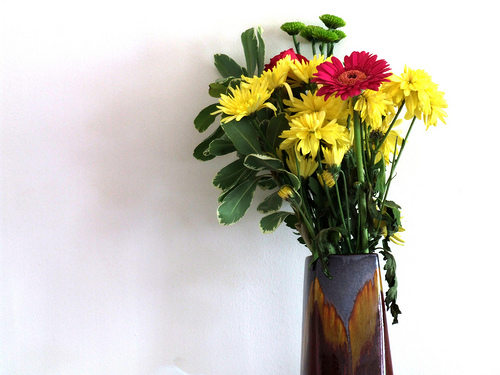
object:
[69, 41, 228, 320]
shadow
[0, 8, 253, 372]
wall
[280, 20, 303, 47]
flower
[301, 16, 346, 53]
flower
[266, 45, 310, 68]
flower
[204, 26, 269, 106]
leaves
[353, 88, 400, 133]
flower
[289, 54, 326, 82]
flower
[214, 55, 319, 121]
flower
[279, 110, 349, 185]
flower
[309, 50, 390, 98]
daisy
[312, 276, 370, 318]
painting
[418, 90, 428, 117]
petals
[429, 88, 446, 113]
petals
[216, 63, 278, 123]
daisies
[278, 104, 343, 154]
daisies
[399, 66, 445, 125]
daisies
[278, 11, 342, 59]
flowers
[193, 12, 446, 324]
bouquet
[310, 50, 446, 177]
flowers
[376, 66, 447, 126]
flower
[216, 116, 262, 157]
leaves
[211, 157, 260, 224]
leaves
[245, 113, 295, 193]
leaves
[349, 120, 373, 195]
stems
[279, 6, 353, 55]
flowers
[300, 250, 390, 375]
vase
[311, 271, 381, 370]
design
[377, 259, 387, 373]
light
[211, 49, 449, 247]
daisies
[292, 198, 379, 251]
stems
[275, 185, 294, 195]
flower